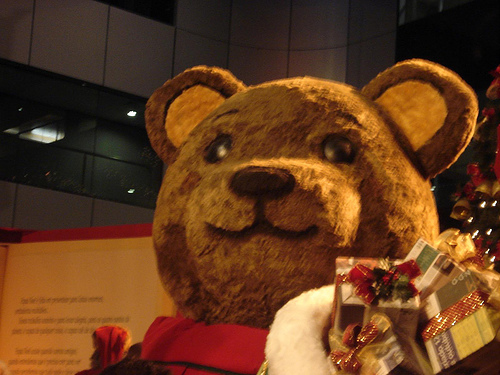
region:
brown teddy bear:
[71, 45, 479, 373]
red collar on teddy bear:
[125, 298, 281, 371]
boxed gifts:
[319, 223, 498, 373]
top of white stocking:
[264, 280, 346, 372]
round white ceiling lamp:
[119, 103, 139, 125]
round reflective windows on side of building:
[5, 59, 167, 208]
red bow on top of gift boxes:
[347, 250, 429, 307]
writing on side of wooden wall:
[6, 272, 141, 374]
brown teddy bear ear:
[357, 45, 485, 185]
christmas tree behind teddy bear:
[443, 57, 497, 278]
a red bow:
[354, 262, 416, 288]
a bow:
[178, 325, 251, 362]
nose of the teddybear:
[231, 170, 291, 190]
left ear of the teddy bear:
[383, 67, 460, 146]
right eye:
[193, 131, 240, 162]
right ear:
[154, 84, 218, 125]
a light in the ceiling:
[124, 108, 140, 124]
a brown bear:
[138, 52, 338, 296]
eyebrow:
[341, 107, 366, 125]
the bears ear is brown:
[379, 75, 467, 162]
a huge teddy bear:
[142, 52, 486, 360]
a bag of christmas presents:
[326, 220, 498, 367]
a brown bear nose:
[226, 165, 302, 203]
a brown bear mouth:
[203, 212, 321, 244]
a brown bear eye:
[199, 123, 236, 165]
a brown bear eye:
[314, 122, 366, 165]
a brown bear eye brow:
[204, 105, 251, 121]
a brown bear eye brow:
[327, 97, 383, 129]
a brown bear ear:
[148, 60, 238, 159]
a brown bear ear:
[358, 55, 481, 183]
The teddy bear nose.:
[229, 165, 307, 205]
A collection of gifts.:
[335, 245, 485, 372]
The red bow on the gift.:
[348, 263, 435, 313]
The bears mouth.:
[199, 213, 341, 253]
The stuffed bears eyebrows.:
[215, 105, 381, 127]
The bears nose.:
[226, 163, 303, 208]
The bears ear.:
[142, 74, 227, 155]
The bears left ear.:
[361, 63, 476, 172]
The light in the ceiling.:
[6, 115, 68, 146]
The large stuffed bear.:
[111, 60, 491, 372]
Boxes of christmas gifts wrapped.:
[327, 233, 495, 373]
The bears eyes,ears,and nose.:
[150, 63, 482, 206]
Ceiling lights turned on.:
[4, 85, 142, 173]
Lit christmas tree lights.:
[463, 182, 497, 274]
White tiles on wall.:
[1, 1, 498, 108]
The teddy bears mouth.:
[196, 213, 330, 240]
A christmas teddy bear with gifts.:
[98, 57, 495, 373]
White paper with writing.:
[2, 230, 177, 373]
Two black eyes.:
[201, 134, 370, 166]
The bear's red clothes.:
[89, 308, 287, 373]